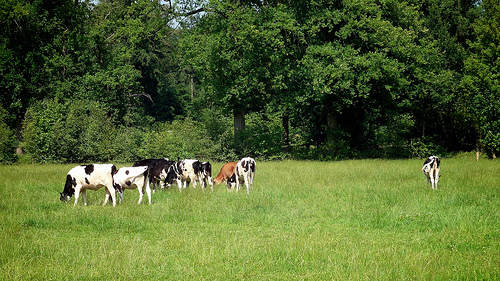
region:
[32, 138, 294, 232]
the cows are eating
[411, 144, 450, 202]
a black and white cow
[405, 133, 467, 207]
a black and white cow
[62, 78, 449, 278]
cows in a field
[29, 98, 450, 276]
cows in a grass field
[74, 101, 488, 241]
cows in a green grass field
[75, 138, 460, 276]
a field with cows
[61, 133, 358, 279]
a green grass field with cows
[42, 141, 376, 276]
a grass field with cows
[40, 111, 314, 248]
cows that are eating grass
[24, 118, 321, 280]
cows eating green grass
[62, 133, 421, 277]
a feild of green grass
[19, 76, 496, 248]
cows walking on the grass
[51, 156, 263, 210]
group of grazing cows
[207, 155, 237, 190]
single brown cow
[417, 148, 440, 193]
black and white cow by itself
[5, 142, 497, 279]
grassy green cow pasture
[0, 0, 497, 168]
dense green forested area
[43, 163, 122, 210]
black and white cow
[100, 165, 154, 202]
black and white cow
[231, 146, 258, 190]
black and white cow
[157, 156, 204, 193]
black and white cow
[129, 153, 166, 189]
black and white cow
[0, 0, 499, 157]
Tall trees in the background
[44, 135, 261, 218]
A group of cows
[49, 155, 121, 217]
A side view of a cow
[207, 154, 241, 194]
A brown cow in the background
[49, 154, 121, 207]
Cow is eating grass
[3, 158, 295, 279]
Cows are standing on grass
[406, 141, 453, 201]
Cow is standing alone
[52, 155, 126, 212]
Cow in the foreground is black and white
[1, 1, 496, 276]
Photo was taken in the daytime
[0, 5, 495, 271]
Photo was taken outdoors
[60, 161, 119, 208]
a black and white cow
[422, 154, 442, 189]
a black and white cow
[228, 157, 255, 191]
a black and white cow eating grass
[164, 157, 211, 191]
a cow eating grass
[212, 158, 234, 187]
a brown cow eating grass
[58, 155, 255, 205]
six cows eating grass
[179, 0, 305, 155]
a big leafy tree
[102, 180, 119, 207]
a cow's rear legs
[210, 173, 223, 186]
a brown cow's head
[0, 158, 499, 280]
a grassy field